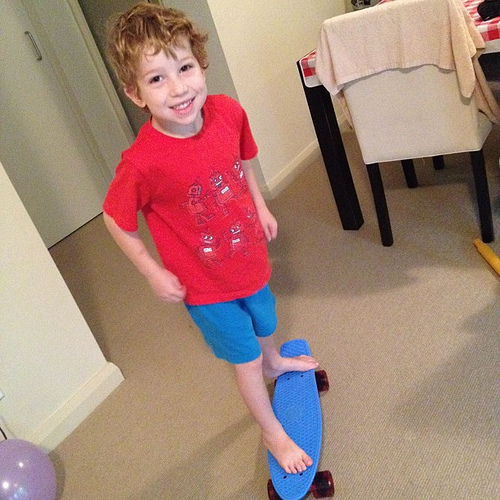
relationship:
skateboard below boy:
[268, 338, 320, 499] [96, 8, 311, 473]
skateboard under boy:
[268, 338, 320, 499] [96, 8, 311, 473]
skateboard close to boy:
[268, 338, 320, 499] [96, 8, 311, 473]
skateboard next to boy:
[268, 338, 320, 499] [96, 8, 311, 473]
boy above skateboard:
[96, 8, 311, 473] [268, 338, 320, 499]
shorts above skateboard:
[179, 284, 299, 357] [268, 338, 320, 499]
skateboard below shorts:
[268, 338, 320, 499] [179, 284, 299, 357]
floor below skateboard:
[21, 100, 472, 499] [268, 338, 320, 499]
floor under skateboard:
[21, 100, 472, 499] [268, 338, 320, 499]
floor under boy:
[21, 100, 472, 499] [96, 8, 311, 473]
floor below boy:
[21, 100, 472, 499] [96, 8, 311, 473]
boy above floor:
[96, 8, 311, 473] [21, 100, 472, 499]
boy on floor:
[96, 8, 311, 473] [21, 100, 472, 499]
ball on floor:
[1, 436, 61, 496] [21, 100, 472, 499]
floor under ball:
[21, 100, 472, 499] [1, 436, 61, 496]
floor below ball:
[21, 100, 472, 499] [1, 436, 61, 496]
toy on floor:
[467, 241, 500, 283] [21, 100, 472, 499]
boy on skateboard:
[96, 8, 311, 473] [268, 338, 320, 499]